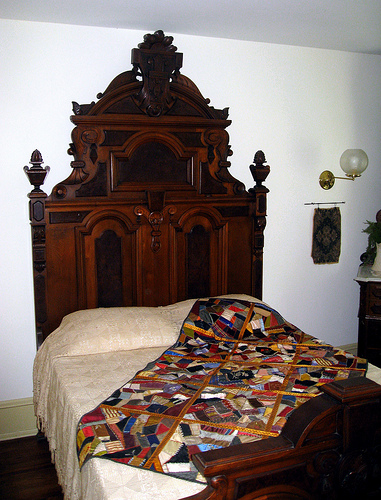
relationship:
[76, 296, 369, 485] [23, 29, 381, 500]
quilt on top of bed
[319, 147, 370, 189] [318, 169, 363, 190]
wall lamp with base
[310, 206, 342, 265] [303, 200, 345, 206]
material hanging from rod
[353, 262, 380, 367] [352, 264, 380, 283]
table with top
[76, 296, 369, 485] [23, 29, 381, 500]
quilt on side of bed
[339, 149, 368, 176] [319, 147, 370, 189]
glass on top of wall lamp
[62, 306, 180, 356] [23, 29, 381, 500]
pillow at head of bed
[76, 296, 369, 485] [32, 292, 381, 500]
quilt laying on bedspread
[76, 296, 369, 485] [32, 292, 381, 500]
quilt resting on bedspread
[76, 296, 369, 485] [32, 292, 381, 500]
quilt sitting on bedspread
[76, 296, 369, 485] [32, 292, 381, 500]
quilt on top of bedspread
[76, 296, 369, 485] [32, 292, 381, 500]
quilt sleeping on bedspread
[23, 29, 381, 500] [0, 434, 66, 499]
bed sitting on floor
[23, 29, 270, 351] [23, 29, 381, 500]
headboard on front of bed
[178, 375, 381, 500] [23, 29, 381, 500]
footboard on base of bed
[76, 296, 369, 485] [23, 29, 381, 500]
quilt laying on bed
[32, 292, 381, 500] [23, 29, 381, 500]
bedspread on top of bed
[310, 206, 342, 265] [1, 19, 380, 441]
material attached to wall